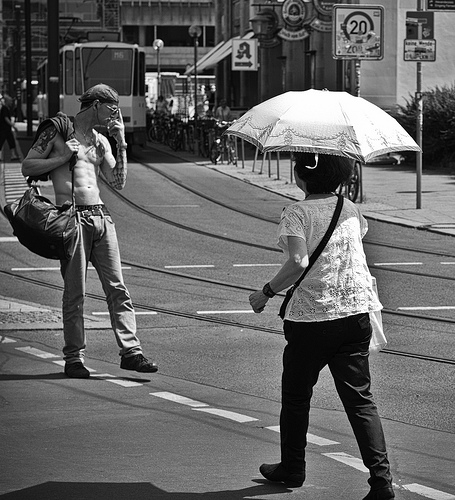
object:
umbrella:
[220, 88, 424, 164]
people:
[3, 81, 160, 381]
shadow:
[1, 477, 293, 499]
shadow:
[0, 371, 150, 384]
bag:
[3, 115, 78, 263]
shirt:
[26, 111, 79, 182]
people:
[248, 143, 395, 500]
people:
[216, 99, 234, 148]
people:
[0, 94, 21, 160]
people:
[155, 94, 173, 124]